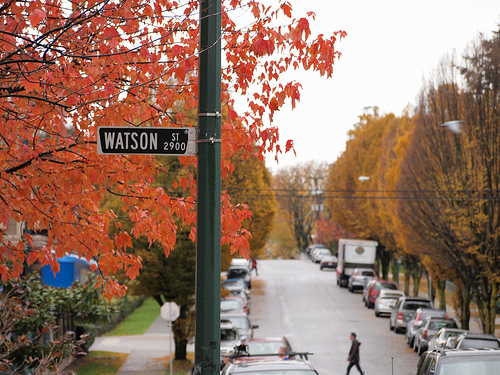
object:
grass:
[96, 294, 166, 337]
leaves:
[128, 35, 134, 43]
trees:
[434, 21, 500, 336]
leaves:
[389, 172, 392, 175]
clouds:
[352, 0, 437, 79]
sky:
[0, 0, 500, 212]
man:
[344, 332, 365, 375]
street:
[247, 259, 421, 375]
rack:
[222, 352, 314, 361]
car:
[221, 352, 322, 375]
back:
[159, 301, 181, 321]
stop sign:
[160, 301, 181, 321]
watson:
[104, 132, 159, 151]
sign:
[96, 126, 199, 157]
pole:
[194, 0, 222, 375]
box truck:
[335, 238, 379, 288]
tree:
[0, 0, 350, 307]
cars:
[374, 288, 406, 317]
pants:
[345, 361, 366, 375]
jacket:
[347, 340, 362, 365]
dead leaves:
[162, 357, 165, 359]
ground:
[63, 295, 196, 375]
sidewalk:
[88, 301, 196, 375]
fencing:
[54, 300, 76, 342]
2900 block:
[163, 142, 185, 151]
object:
[41, 251, 101, 289]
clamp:
[196, 137, 222, 145]